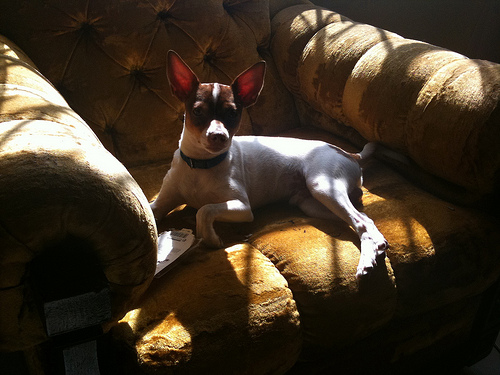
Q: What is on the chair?
A: A dog.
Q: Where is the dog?
A: On the chair.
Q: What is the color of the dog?
A: White and brown.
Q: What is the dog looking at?
A: The camera.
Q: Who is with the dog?
A: No one.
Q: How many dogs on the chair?
A: One.